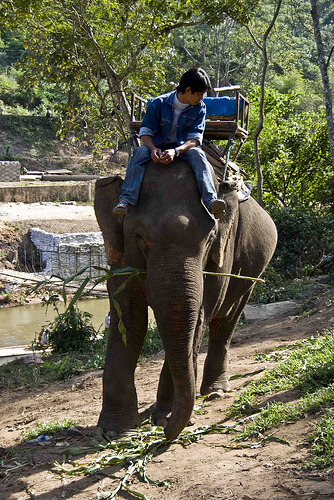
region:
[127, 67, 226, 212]
man on an elephant's head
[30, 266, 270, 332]
elephant holding a grassy stalk in it's mouth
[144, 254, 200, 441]
long gray elephant trunk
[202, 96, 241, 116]
blue blanket on a seat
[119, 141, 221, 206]
boy wearing jeans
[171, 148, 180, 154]
boy wearing a watch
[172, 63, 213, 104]
boy with black hair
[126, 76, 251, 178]
chair on elephant's back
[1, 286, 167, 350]
water near an elephant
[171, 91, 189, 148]
man wearing a white turtleneck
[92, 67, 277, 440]
a guy sitting on top of an elephant.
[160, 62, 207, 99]
boy has brown hair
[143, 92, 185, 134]
boy has white shirt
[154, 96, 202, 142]
boy has blue shirt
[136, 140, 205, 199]
boy has blue pants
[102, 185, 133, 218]
boy has blue shoes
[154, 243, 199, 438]
elephant has wide trunk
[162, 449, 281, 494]
brown and dry ground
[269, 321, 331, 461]
green grass on ground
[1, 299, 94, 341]
brown water behind elephant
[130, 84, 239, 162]
brown seat on elephant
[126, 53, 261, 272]
boy on an elephant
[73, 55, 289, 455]
an elephant carry a man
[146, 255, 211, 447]
long trunk of elephant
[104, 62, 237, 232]
man sits on head of elephant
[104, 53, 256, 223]
a bench and a man on back an elephant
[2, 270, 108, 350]
a river with brown water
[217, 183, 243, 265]
right ear of elephant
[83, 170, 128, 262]
left ear of elephant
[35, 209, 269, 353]
elephant has a stick on mouth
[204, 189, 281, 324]
belly of elephant is bulky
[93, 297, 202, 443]
front legs of elephant